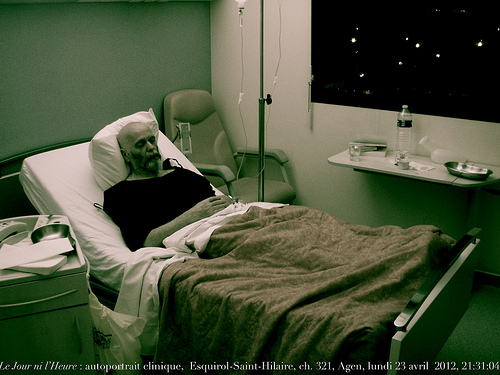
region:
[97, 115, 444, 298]
Man in a bed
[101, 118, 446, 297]
Man is in a bed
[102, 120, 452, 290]
Man in a hospital bed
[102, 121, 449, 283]
Man is in a hospital bed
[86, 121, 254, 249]
Man under a blanket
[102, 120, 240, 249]
Man is under a blanket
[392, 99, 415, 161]
Bottle on a shelf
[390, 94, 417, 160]
Bottle is on a shelf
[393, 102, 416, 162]
Bottle of water on a shelf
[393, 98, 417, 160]
Bottle of water is on a shelf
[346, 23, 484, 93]
Lights shining outside of the window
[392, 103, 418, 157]
A plastic water bottle on the table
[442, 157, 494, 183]
A small silver bed pan on the table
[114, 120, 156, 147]
The man has no hair on his head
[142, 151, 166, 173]
The man has a white goatee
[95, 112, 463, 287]
A very ill man lying in a hospital bed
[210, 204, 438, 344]
A brown blanket on the man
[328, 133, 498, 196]
A small white table by the wall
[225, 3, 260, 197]
Thin plastic tubing by the bed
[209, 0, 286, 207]
An IV drip attached to the sickly man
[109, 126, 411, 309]
a man laying in a hospital bed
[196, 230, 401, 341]
brown comforter of the bed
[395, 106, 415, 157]
a water bottle on the counter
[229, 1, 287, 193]
IV tubes handing from a grey metal post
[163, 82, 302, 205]
an empty chair in the corner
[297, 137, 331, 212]
white walls of the hospital room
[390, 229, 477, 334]
black rail on the end of the bed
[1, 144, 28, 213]
black headboard of the hospital bed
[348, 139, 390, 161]
a book setting on the counter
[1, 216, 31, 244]
a white phone on a rolling cart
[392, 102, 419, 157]
a plastic water bottle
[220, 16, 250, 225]
a iv line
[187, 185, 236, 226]
a man with his hands folded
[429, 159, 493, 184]
a metal bed pan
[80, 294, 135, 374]
a plastic bag hanging on a table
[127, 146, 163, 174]
a man with facial hair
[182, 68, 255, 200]
a hospital chair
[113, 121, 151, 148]
a man with no hair on his head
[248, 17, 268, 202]
a metal iv stand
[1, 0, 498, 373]
Hospital room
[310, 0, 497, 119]
Window in the hospital room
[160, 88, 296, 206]
Chair next to the hospital bed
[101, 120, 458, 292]
Man resting in the hospital red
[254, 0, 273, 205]
Pole used to hold IV lines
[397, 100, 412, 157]
Empty bottle of water on the counter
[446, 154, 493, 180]
Empty plate on the counter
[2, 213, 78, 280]
Personal supplies on the dresser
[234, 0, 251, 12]
Pouch with fluids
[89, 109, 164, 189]
Pillow behind the man's head